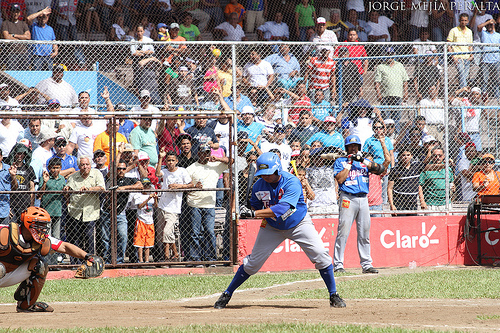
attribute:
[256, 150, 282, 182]
helmet — blue, black, orange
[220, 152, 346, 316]
player — swinging bat, waiting, wearing, preparing, standing, holding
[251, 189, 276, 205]
logo — white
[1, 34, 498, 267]
fence — chain link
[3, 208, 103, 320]
catcher — waiting, crouched down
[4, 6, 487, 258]
audience — watching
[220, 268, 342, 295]
socks — blue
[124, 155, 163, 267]
man — sitting down, playing, leaning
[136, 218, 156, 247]
shorts — orange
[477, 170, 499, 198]
shirt — orange, striped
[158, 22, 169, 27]
hat — blue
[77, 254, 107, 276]
glove — black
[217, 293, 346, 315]
shoe — black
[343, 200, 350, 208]
sign — red